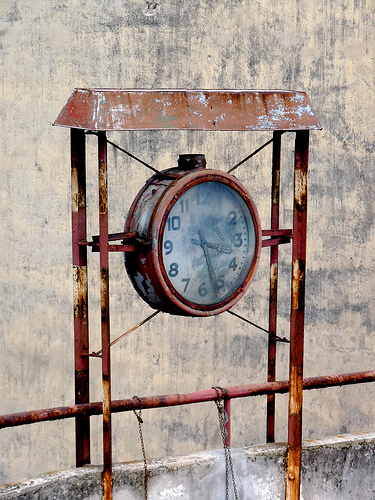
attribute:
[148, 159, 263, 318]
clock — dirk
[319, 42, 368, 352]
wall — dirty, cement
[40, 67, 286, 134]
roof — tin, white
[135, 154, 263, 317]
clock — round, metal, numbered, dirty, rusty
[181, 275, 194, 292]
numbers — black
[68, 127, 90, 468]
bar — rusty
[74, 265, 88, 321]
paint — two tone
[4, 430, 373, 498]
wall — discolored, cement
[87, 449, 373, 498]
paint — white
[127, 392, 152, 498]
chain — black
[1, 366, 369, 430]
pole — red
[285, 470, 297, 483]
screw — large, gold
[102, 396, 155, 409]
soot — black, red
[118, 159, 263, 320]
clock — round, metal, rusty, dirty, numbered, old, pictured, large, red, chipped, 3:27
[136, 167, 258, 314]
clock — fogged-over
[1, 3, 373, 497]
wall — stained, gray, concrete, scratched-up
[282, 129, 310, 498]
metal rod — old, rusted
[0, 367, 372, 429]
railing — red, rusty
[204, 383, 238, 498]
chain — rusty, thin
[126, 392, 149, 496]
chain — rusty, thin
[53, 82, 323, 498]
clock post — red, rusty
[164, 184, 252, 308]
glass — cloudy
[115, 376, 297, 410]
bar — metal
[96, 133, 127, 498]
pole — rusted, metal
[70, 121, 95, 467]
pole — metal, rusted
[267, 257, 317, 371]
bars — RUSTED, METAL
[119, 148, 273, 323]
clock — strung between tin rods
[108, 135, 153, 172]
rods — tin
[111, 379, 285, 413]
rod — metal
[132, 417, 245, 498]
wire — hanging off a metal rod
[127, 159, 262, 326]
cover — rusted